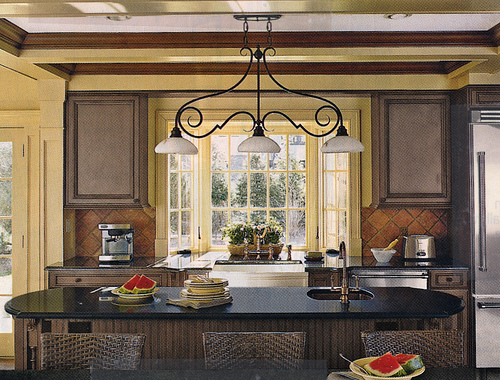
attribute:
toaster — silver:
[397, 227, 437, 265]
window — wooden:
[162, 113, 377, 272]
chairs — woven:
[33, 328, 476, 374]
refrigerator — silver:
[455, 92, 499, 364]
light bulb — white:
[321, 134, 367, 153]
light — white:
[151, 108, 368, 157]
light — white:
[234, 123, 279, 161]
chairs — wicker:
[38, 330, 464, 369]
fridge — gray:
[459, 110, 498, 370]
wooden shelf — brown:
[66, 90, 156, 214]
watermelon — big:
[363, 347, 408, 379]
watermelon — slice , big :
[115, 270, 160, 291]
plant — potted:
[233, 218, 283, 240]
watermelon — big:
[121, 267, 176, 307]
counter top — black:
[4, 287, 464, 319]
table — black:
[234, 287, 316, 330]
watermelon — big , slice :
[361, 350, 404, 377]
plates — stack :
[158, 261, 235, 318]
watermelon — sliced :
[130, 275, 157, 293]